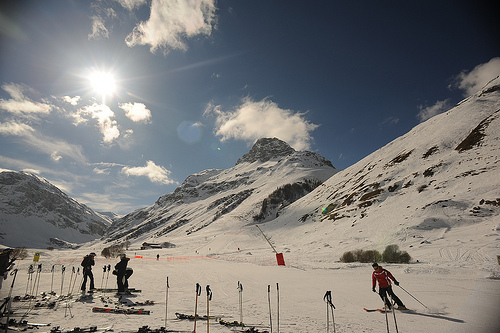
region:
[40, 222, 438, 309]
People skiing on a beautiful sunny day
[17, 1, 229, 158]
Just a few clouds in the sky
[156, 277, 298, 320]
Ski poles stuck in the snow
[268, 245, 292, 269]
An orange barrel i the snow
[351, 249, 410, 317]
A person in a red coat skiing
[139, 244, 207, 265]
Orange cones in the snow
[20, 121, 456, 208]
Small mountains covered in snow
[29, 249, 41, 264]
A yellow sign in the snow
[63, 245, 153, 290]
Three people getting ready to ski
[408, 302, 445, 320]
Snow is flying behind the skier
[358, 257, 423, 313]
skier wearing red coat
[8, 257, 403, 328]
ski poles stuck in the snow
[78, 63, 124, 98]
sun glaring in the sky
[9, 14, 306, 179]
white clouds scattered in the sky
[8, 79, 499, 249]
three snow covered mountaintops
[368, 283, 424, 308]
ski poles of person in red jacket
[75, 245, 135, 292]
two peopel standing among ski poles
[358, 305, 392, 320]
skis of person wearing red coat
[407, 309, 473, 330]
shadow of person wearing red coat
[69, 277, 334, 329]
tracks in the snow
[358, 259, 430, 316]
skier in red on right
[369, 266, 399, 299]
red winter ski jacket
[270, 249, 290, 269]
orange marker on slope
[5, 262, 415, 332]
row of ski poles in snow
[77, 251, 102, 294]
man walking to the right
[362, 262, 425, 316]
skier skiing to the left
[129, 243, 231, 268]
distant orange boundary fence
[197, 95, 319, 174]
cloud atop high mountain peak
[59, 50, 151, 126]
bright sun in blue partly cloudy sky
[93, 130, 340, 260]
tall mountain in background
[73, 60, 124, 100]
very bright sun in the sky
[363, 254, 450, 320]
person zooming through the snow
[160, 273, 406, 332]
sets of poles stuck in the snow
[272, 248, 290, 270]
red marker in the snow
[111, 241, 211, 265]
orange boundaries set up in snow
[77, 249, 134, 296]
two more people about to go skiing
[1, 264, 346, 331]
snow gear left unattended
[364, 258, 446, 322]
using poles to push through snow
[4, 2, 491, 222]
clear blue beautiful skies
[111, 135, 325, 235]
very steep mountain covered in snow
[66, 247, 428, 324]
People standing on a ski slope.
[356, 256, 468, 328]
A person skiing.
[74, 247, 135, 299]
Two people standing near ski poles.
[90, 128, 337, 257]
A snow-covered mountain.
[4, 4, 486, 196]
Blue sky with white clouds.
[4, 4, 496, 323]
People skiing during the day.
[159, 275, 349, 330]
Ski poles in the snow.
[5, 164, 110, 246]
Mountain in the distance.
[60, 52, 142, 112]
Bright sun shining in the sky.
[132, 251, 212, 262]
Orange fence in the distance.